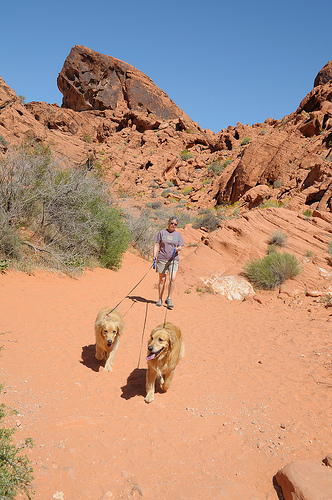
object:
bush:
[240, 246, 304, 291]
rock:
[272, 456, 331, 498]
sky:
[0, 1, 332, 128]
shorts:
[155, 257, 178, 273]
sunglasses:
[168, 221, 180, 228]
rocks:
[204, 272, 251, 305]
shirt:
[155, 225, 186, 261]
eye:
[112, 328, 116, 332]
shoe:
[164, 296, 173, 310]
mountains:
[0, 44, 331, 271]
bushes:
[0, 138, 131, 276]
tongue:
[146, 351, 156, 360]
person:
[154, 217, 183, 309]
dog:
[143, 319, 184, 403]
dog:
[94, 307, 123, 373]